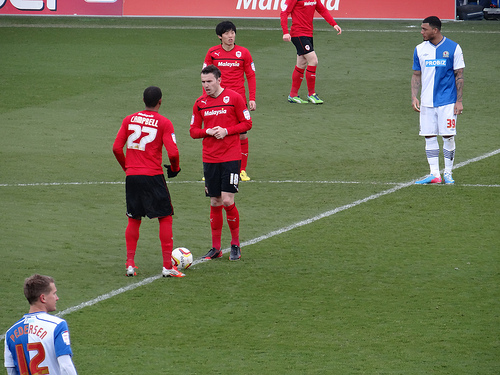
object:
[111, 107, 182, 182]
red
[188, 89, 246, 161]
jersey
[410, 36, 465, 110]
blue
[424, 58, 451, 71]
logo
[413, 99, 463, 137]
white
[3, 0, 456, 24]
wall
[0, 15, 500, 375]
field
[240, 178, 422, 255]
white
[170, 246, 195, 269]
ball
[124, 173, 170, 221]
black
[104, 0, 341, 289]
soccer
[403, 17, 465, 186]
players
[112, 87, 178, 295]
player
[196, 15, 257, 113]
asian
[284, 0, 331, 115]
player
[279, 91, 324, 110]
yellow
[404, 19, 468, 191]
player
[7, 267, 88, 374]
player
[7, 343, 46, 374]
12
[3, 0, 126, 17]
signs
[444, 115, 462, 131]
number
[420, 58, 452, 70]
writing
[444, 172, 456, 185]
blue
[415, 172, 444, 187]
cleats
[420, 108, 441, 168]
leg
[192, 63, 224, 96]
head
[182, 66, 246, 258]
player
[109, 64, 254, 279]
talking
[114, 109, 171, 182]
back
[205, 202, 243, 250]
red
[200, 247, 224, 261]
black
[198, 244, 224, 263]
cleats